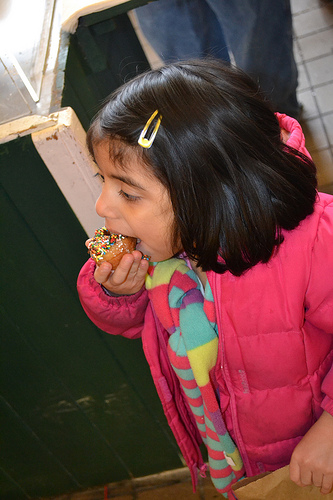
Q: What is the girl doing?
A: Eating.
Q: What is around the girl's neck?
A: A scarf.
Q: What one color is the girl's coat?
A: Pink.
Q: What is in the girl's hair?
A: A barrette.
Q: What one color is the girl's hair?
A: Black.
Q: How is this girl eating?
A: With her hands.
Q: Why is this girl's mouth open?
A: She is eating.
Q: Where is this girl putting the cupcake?
A: In her mouth.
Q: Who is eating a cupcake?
A: Little girl.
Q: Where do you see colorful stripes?
A: On the girl's scarf.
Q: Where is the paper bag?
A: The girl's left hand.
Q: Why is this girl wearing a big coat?
A: It is cold weather.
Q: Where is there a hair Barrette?
A: In the girl's hair.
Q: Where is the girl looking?
A: To her right.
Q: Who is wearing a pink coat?
A: The little girl.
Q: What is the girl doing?
A: Eating.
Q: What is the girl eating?
A: A donut.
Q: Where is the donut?
A: In the girl's hand.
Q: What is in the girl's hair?
A: A hair clip.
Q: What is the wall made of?
A: Wood.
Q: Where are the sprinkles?
A: On the donut.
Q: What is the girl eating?
A: A donut.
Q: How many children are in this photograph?
A: One.